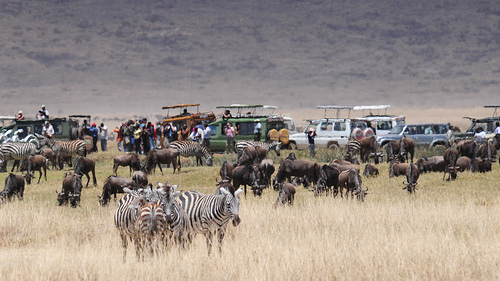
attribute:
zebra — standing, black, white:
[155, 180, 249, 228]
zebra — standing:
[113, 187, 155, 258]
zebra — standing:
[155, 183, 190, 248]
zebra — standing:
[175, 184, 245, 258]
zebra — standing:
[168, 139, 215, 168]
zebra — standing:
[236, 137, 282, 157]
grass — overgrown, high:
[241, 191, 496, 280]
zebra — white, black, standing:
[106, 189, 152, 261]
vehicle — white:
[286, 114, 376, 156]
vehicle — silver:
[402, 111, 472, 153]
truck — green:
[165, 102, 295, 178]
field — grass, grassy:
[2, 206, 498, 279]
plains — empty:
[1, 0, 499, 122]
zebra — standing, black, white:
[231, 139, 283, 168]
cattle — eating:
[1, 136, 498, 204]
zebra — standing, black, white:
[0, 136, 42, 170]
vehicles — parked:
[21, 109, 478, 171]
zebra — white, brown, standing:
[165, 185, 245, 254]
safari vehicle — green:
[200, 102, 295, 164]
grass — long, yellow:
[1, 137, 498, 279]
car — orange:
[158, 102, 200, 138]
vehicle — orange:
[149, 93, 237, 178]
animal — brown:
[0, 170, 30, 200]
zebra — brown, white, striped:
[45, 137, 90, 165]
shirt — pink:
[222, 125, 235, 135]